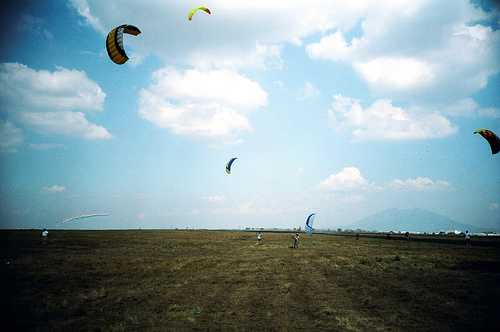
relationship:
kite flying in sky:
[105, 23, 141, 63] [0, 0, 497, 232]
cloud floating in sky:
[137, 65, 269, 145] [0, 0, 497, 232]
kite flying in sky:
[187, 5, 213, 21] [0, 0, 497, 232]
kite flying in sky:
[224, 156, 238, 175] [0, 0, 497, 232]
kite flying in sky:
[473, 128, 499, 154] [0, 0, 497, 232]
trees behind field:
[244, 228, 339, 234] [2, 228, 497, 331]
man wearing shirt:
[41, 227, 50, 245] [41, 230, 49, 236]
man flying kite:
[41, 227, 50, 245] [105, 23, 141, 63]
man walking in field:
[41, 227, 50, 245] [2, 228, 497, 331]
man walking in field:
[291, 232, 302, 249] [2, 228, 497, 331]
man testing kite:
[41, 227, 50, 245] [105, 23, 141, 63]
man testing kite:
[291, 232, 302, 249] [224, 156, 238, 175]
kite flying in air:
[105, 23, 141, 63] [0, 0, 497, 232]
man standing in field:
[41, 227, 50, 245] [2, 228, 497, 331]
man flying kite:
[291, 232, 302, 249] [224, 156, 238, 175]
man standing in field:
[291, 232, 302, 249] [2, 228, 497, 331]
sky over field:
[0, 0, 497, 232] [2, 228, 497, 331]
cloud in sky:
[137, 65, 269, 145] [0, 0, 497, 232]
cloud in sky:
[11, 107, 115, 140] [0, 0, 497, 232]